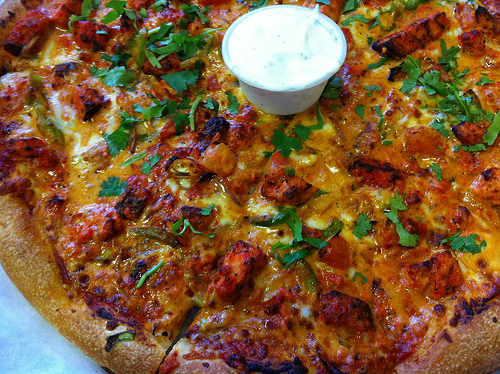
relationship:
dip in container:
[230, 7, 330, 84] [219, 3, 349, 117]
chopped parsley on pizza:
[104, 11, 211, 128] [0, 0, 498, 372]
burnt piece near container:
[197, 112, 229, 152] [219, 3, 349, 117]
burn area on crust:
[222, 355, 311, 372] [161, 283, 497, 372]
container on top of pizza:
[219, 3, 349, 117] [0, 0, 498, 372]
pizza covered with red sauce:
[0, 0, 498, 372] [202, 214, 300, 342]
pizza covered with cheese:
[0, 0, 498, 372] [39, 9, 499, 282]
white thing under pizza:
[12, 307, 68, 373] [0, 0, 498, 372]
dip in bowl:
[230, 7, 330, 84] [219, 4, 349, 119]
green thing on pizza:
[289, 257, 324, 306] [0, 0, 498, 372]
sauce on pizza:
[204, 242, 275, 305] [0, 0, 498, 372]